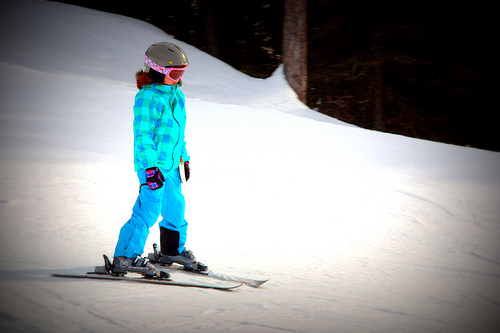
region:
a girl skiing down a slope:
[30, 17, 408, 314]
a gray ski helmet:
[125, 31, 200, 66]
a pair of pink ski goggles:
[142, 51, 183, 82]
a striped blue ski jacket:
[110, 78, 210, 173]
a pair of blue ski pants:
[105, 170, 210, 257]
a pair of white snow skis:
[51, 244, 273, 307]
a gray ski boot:
[103, 245, 160, 280]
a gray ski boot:
[139, 243, 204, 277]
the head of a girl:
[134, 37, 191, 87]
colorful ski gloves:
[136, 158, 168, 196]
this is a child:
[48, 25, 275, 325]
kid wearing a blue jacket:
[126, 84, 213, 176]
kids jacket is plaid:
[125, 87, 192, 167]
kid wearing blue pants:
[129, 147, 199, 255]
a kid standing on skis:
[63, 27, 252, 307]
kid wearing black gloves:
[142, 151, 204, 191]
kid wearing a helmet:
[145, 27, 199, 85]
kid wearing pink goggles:
[142, 53, 194, 89]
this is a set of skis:
[63, 251, 271, 309]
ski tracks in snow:
[279, 192, 463, 315]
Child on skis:
[45, 244, 275, 302]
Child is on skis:
[46, 246, 273, 296]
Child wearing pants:
[112, 155, 192, 259]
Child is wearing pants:
[115, 161, 189, 262]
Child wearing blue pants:
[110, 161, 193, 261]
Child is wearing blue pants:
[111, 159, 193, 262]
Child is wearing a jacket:
[134, 80, 191, 176]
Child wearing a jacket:
[133, 82, 190, 169]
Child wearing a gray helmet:
[142, 28, 189, 80]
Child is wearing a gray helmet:
[139, 37, 189, 77]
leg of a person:
[119, 174, 168, 249]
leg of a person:
[151, 185, 213, 257]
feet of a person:
[94, 256, 159, 290]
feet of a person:
[149, 232, 217, 267]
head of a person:
[128, 30, 210, 100]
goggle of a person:
[159, 57, 204, 79]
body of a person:
[105, 65, 211, 186]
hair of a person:
[134, 64, 153, 81]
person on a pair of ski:
[62, 27, 250, 292]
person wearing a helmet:
[123, 27, 251, 112]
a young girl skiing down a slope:
[56, 25, 442, 310]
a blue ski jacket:
[99, 75, 201, 163]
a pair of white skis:
[51, 258, 271, 303]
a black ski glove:
[141, 165, 165, 190]